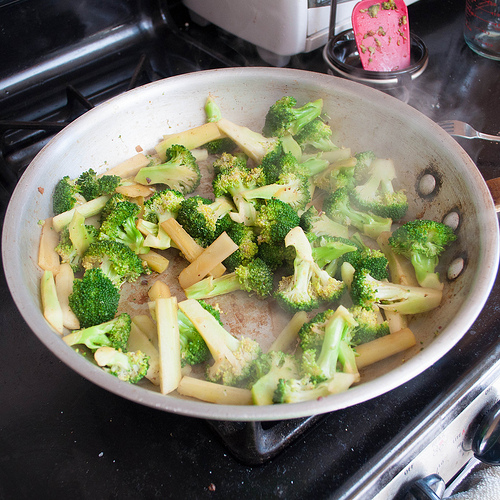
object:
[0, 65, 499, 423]
pan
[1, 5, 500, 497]
stove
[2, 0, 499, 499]
kitchen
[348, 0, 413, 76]
spatula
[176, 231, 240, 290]
potatoes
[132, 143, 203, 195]
broccoli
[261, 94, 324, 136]
pieces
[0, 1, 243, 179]
burner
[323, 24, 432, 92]
bowl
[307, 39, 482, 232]
steam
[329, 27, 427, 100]
mug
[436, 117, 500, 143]
fork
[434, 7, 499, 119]
cup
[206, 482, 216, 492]
crumb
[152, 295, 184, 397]
bamboo shoots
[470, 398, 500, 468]
controls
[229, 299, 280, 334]
brown stuff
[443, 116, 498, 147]
utensil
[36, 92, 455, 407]
stir fry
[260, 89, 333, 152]
vegetables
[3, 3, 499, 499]
counter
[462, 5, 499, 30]
measuring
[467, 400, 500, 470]
knobs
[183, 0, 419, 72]
appliance